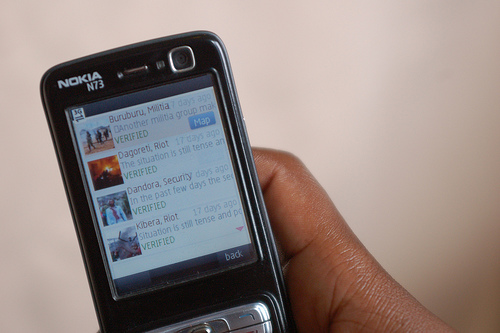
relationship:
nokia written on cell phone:
[54, 72, 107, 90] [37, 31, 277, 333]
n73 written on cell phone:
[85, 78, 108, 93] [37, 31, 277, 333]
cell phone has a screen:
[37, 31, 277, 333] [85, 92, 252, 273]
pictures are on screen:
[77, 125, 146, 265] [85, 92, 252, 273]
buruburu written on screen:
[109, 109, 145, 120] [85, 92, 252, 273]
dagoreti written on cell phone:
[113, 141, 161, 160] [37, 31, 277, 333]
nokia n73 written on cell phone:
[54, 72, 107, 90] [37, 31, 277, 333]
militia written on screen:
[146, 103, 171, 114] [85, 92, 252, 273]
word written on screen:
[225, 247, 249, 266] [85, 92, 252, 273]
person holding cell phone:
[263, 134, 401, 332] [37, 31, 277, 333]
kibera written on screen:
[134, 218, 161, 230] [85, 92, 252, 273]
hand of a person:
[270, 157, 424, 332] [263, 134, 401, 332]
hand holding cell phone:
[270, 157, 424, 332] [37, 31, 277, 333]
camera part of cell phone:
[168, 44, 198, 73] [37, 31, 277, 333]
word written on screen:
[122, 163, 162, 179] [85, 92, 252, 273]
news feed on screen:
[94, 120, 228, 246] [85, 92, 252, 273]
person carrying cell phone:
[263, 134, 401, 332] [37, 31, 277, 333]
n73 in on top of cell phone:
[85, 78, 108, 93] [37, 31, 277, 333]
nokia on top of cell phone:
[54, 72, 107, 90] [37, 31, 277, 333]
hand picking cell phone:
[270, 157, 424, 332] [37, 31, 277, 333]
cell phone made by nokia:
[37, 31, 277, 333] [54, 72, 107, 90]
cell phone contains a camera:
[37, 31, 277, 333] [168, 44, 198, 73]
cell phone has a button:
[37, 31, 277, 333] [225, 304, 268, 325]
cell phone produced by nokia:
[37, 31, 277, 333] [54, 72, 107, 90]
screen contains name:
[85, 92, 252, 273] [107, 101, 173, 123]